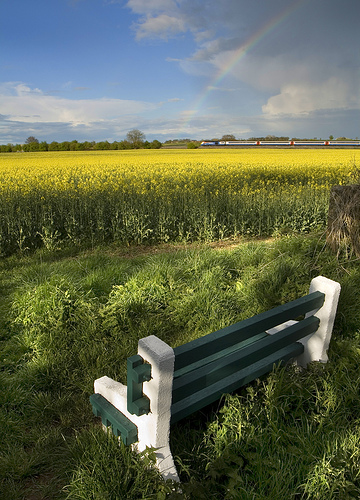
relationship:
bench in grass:
[89, 274, 341, 497] [1, 233, 345, 498]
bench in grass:
[89, 274, 341, 497] [30, 263, 214, 329]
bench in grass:
[89, 274, 341, 497] [102, 401, 335, 488]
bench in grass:
[47, 263, 351, 456] [41, 231, 219, 293]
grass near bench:
[1, 233, 345, 498] [89, 274, 341, 497]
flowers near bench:
[0, 147, 359, 255] [89, 274, 341, 497]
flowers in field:
[0, 147, 359, 255] [2, 141, 352, 448]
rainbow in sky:
[183, 2, 297, 132] [79, 19, 167, 86]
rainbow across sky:
[183, 2, 297, 132] [0, 0, 347, 142]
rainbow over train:
[183, 2, 297, 132] [198, 137, 348, 146]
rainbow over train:
[183, 2, 297, 132] [197, 138, 348, 150]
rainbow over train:
[183, 2, 297, 132] [181, 120, 339, 158]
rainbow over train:
[183, 2, 297, 132] [197, 138, 348, 147]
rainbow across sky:
[183, 2, 297, 132] [213, 84, 264, 122]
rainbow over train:
[183, 2, 297, 132] [217, 137, 292, 148]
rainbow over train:
[183, 2, 297, 132] [198, 137, 355, 152]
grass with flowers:
[1, 150, 358, 259] [0, 147, 348, 185]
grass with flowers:
[1, 233, 345, 498] [0, 147, 359, 255]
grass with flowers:
[1, 194, 346, 233] [0, 148, 358, 189]